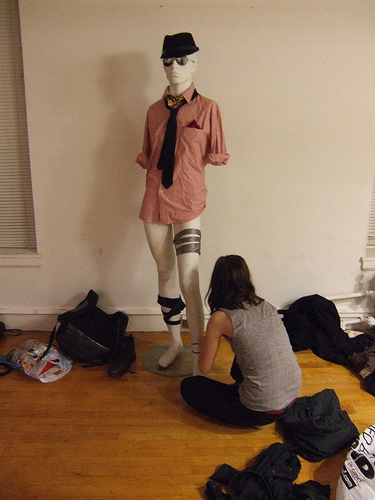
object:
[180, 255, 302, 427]
woman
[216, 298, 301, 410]
shirt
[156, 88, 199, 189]
tie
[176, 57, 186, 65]
glass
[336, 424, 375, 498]
bag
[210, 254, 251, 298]
head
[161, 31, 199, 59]
hat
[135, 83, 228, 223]
shirt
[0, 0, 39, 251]
window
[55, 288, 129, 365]
backpack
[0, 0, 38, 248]
blind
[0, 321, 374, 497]
floor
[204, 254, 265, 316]
hair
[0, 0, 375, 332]
wall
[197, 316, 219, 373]
arm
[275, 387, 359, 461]
clothe